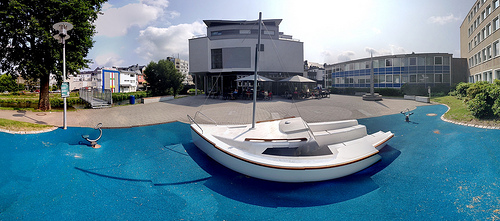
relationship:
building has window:
[460, 0, 499, 88] [256, 43, 266, 53]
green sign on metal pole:
[60, 82, 69, 97] [57, 35, 81, 125]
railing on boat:
[241, 134, 311, 144] [173, 107, 403, 182]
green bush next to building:
[465, 87, 495, 117] [460, 0, 499, 88]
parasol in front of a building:
[276, 72, 318, 84] [185, 12, 310, 93]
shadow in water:
[233, 190, 359, 215] [7, 125, 497, 219]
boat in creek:
[187, 116, 397, 183] [2, 104, 474, 211]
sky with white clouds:
[1, 2, 476, 83] [89, 1, 206, 65]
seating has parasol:
[232, 85, 323, 102] [234, 74, 275, 82]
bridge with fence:
[79, 86, 113, 109] [45, 65, 147, 113]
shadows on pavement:
[218, 87, 305, 119] [7, 79, 439, 137]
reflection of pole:
[65, 156, 224, 188] [235, 9, 275, 138]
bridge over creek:
[80, 85, 116, 109] [0, 103, 474, 211]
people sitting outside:
[242, 82, 324, 101] [5, 6, 469, 204]